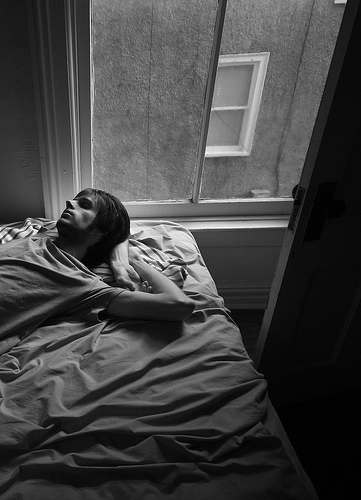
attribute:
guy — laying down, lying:
[1, 186, 201, 332]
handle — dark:
[303, 176, 346, 242]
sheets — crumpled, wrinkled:
[3, 216, 305, 497]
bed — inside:
[1, 216, 320, 498]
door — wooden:
[253, 1, 358, 409]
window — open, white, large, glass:
[72, 3, 347, 218]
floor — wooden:
[230, 302, 359, 499]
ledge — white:
[127, 199, 295, 238]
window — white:
[198, 45, 279, 166]